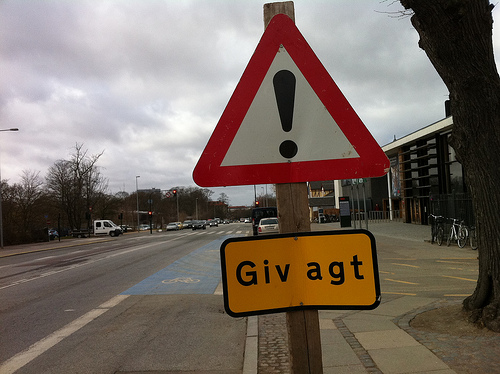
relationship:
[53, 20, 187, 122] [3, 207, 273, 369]
clouds above land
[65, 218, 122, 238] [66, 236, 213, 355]
truck on street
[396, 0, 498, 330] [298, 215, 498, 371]
tree trunk on sidewalk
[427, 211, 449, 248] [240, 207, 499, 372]
bike near sidewalk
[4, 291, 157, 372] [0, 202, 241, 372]
line near road